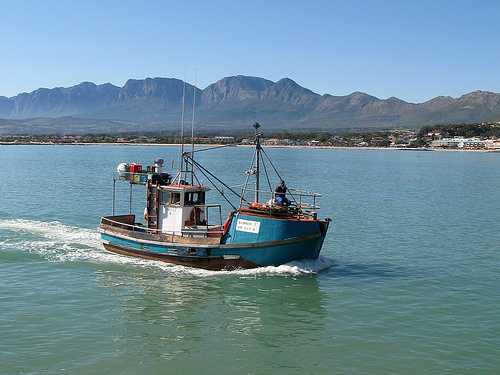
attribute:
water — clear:
[1, 216, 392, 371]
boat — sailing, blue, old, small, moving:
[66, 146, 367, 292]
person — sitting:
[248, 171, 308, 216]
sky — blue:
[13, 5, 455, 105]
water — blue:
[11, 145, 478, 302]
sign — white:
[228, 215, 275, 239]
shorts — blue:
[271, 193, 292, 207]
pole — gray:
[174, 61, 202, 185]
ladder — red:
[137, 179, 168, 235]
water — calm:
[325, 155, 499, 262]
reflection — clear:
[41, 259, 383, 347]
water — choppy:
[4, 204, 168, 280]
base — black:
[75, 234, 334, 276]